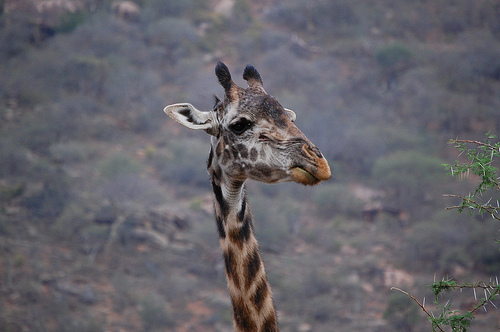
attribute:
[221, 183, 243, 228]
patch — white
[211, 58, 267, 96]
horns — two black tipped giraffe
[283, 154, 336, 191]
mouth — giraffe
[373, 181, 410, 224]
ground — rear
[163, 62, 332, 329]
giraffe — looking , stationary , glances off , big tall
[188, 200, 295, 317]
neck — long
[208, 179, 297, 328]
neck — long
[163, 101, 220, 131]
ear — white, black inside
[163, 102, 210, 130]
ears — perked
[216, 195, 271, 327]
spots — giraffe, peach ,  black orange 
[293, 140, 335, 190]
nose — brown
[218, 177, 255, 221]
throat — upper 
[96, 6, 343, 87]
terraine — rocky 